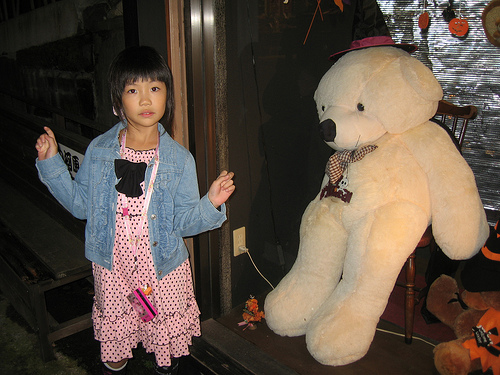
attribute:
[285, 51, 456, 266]
bear — brown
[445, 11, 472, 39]
jack-o-lantern — orange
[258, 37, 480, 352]
bear — big, brown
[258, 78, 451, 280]
bear — large, tan colored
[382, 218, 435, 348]
chair — wood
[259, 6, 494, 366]
stuffed bear — white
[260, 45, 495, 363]
ribbon — plaid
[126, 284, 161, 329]
purse — small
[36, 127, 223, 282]
jacket — light blue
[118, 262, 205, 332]
dress — pink, polka dots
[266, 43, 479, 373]
bear — brown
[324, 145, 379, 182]
ribbon — brown, gingham 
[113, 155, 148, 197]
bow — black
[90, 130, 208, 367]
dress — pink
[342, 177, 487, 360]
chair — brown, wooden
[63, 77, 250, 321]
dress — pink, polka dots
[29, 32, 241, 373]
girl — young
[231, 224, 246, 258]
outlet — electrical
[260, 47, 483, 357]
teddy bear — large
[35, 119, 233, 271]
jacket — blue